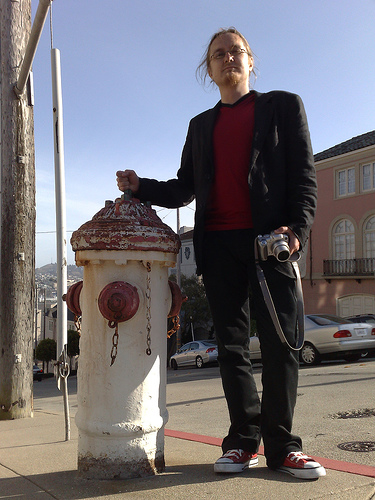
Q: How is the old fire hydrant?
A: Red and white.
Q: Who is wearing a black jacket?
A: A man.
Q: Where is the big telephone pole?
A: Behind the fire hydrant.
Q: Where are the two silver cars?
A: Other side.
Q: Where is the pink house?
A: Across street.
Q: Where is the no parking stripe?
A: On curb.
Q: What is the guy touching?
A: Hydrant.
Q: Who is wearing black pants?
A: The man.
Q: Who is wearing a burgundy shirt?
A: The man.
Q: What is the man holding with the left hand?
A: A camera.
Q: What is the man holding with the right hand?
A: A fire hydrant.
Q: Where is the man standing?
A: On a sidewalk.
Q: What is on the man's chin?
A: A goatee.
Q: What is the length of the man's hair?
A: Long.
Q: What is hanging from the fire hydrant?
A: Chains.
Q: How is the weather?
A: Clear.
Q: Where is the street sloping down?
A: To the left.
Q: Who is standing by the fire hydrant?
A: The man with glasses.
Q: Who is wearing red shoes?
A: The man by the fire hydrant.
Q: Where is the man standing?
A: On the sidewalk.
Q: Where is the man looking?
A: At the photographer.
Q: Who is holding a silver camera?
A: The man with the black jacket.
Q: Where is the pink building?
A: Behind the parked cars.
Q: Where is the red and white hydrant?
A: Next to the man on the sidewalk.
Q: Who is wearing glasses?
A: The man wearing black pants.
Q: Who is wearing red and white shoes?
A: The man looking at the photographer.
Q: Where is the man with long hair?
A: Standing outside on a sidewalk.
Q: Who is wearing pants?
A: A man.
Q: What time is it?
A: Afternoon.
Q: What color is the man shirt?
A: Red.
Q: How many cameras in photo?
A: One.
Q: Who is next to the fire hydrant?
A: A man.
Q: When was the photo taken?
A: Day time.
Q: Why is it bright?
A: Sunny.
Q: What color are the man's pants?
A: Black.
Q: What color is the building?
A: Peach.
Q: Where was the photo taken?
A: On the street.